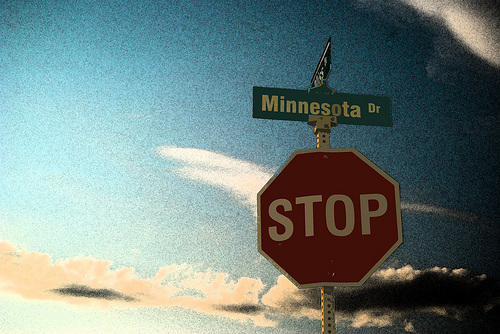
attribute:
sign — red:
[262, 156, 412, 280]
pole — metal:
[315, 296, 341, 319]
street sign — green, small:
[259, 80, 400, 149]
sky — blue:
[96, 19, 183, 75]